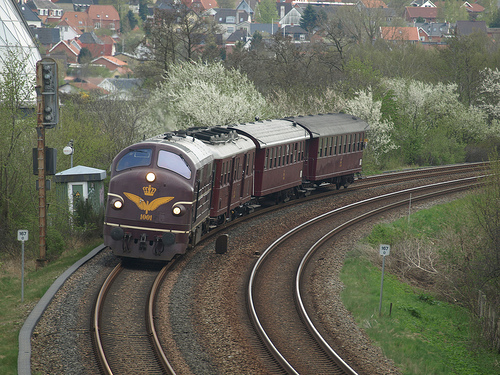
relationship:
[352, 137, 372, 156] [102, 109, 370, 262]
window on train car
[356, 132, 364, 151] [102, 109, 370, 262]
window on train car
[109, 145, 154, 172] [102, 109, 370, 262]
window on train car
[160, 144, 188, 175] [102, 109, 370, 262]
window on train car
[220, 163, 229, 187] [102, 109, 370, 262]
window on train car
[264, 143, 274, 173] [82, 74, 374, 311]
window on train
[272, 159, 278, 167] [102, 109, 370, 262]
window on train car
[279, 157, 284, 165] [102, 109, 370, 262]
window on train car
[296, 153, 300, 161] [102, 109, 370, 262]
window on train car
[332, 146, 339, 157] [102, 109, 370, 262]
window on train car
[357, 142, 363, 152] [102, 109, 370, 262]
window on train car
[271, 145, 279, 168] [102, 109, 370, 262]
window on train car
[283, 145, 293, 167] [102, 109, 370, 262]
window on train car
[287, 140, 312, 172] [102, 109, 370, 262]
window on train car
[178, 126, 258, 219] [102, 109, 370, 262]
train car on train car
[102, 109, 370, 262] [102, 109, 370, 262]
train car on train car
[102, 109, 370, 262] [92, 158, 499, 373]
train car on train tracks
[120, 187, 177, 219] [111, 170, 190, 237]
golden bird on train engine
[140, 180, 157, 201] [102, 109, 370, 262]
crown on train car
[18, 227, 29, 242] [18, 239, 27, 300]
sign on pole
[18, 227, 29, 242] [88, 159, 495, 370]
sign next to tracks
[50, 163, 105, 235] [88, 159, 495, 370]
building next to tracks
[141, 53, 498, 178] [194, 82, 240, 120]
tree have blossoms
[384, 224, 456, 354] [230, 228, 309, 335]
grass next to tracks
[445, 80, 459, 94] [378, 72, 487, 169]
leaf on tree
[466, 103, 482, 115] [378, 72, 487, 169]
leaf on tree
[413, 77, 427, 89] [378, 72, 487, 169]
leaf on tree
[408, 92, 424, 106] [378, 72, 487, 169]
leaf on tree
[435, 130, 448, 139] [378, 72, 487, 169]
leaf on tree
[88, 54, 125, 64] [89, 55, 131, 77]
roof on house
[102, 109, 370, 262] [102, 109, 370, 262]
train car a train car